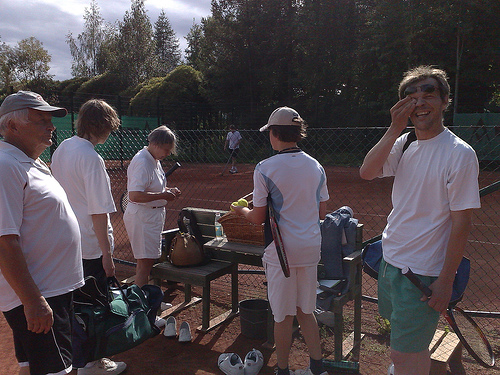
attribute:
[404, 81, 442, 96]
sunglasses — black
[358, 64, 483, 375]
man — standing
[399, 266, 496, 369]
racket — held, tennis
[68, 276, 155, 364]
bag — green, blue, black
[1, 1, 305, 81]
skies — cloudy, gray, white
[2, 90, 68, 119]
cap — man, baseball, gray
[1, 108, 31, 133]
hair — white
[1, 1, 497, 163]
trees — green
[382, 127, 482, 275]
shirt — white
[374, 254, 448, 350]
shorts — green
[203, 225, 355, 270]
table — filled, wooden, brown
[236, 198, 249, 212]
balls — green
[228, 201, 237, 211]
balls — green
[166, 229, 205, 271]
bag — tan, brown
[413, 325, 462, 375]
bench — covered, wooden, brown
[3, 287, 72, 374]
shorts — white, black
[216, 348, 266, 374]
shoes — white, empty, tennis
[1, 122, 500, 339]
fence — chain link, metal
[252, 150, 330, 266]
shirt — white, blue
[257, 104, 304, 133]
hat — tan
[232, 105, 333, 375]
man — wearing blue, wearing white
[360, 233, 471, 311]
bag — black, blue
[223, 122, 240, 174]
man — playing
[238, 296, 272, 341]
bucket — wooden